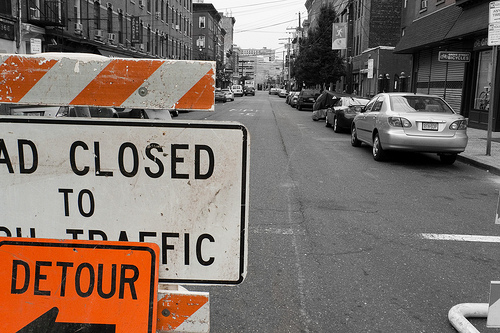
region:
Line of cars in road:
[264, 74, 466, 165]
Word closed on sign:
[68, 136, 220, 193]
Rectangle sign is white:
[1, 119, 244, 288]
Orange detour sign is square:
[8, 249, 155, 326]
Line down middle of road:
[265, 99, 321, 331]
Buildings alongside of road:
[6, 0, 227, 42]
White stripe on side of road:
[408, 212, 499, 257]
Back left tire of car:
[367, 117, 398, 162]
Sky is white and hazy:
[218, 2, 295, 94]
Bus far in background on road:
[241, 74, 260, 99]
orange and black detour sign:
[3, 230, 156, 330]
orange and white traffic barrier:
[3, 49, 227, 331]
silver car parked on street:
[349, 89, 465, 171]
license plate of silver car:
[419, 118, 436, 140]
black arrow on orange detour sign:
[8, 298, 126, 332]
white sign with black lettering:
[2, 118, 253, 283]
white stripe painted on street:
[411, 221, 499, 249]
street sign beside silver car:
[472, 2, 499, 154]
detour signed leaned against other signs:
[0, 232, 165, 332]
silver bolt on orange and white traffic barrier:
[131, 81, 154, 98]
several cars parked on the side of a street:
[257, 3, 496, 332]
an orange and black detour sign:
[2, 238, 159, 329]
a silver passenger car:
[351, 90, 473, 167]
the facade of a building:
[400, 5, 495, 95]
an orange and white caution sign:
[2, 48, 219, 117]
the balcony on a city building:
[21, 0, 68, 31]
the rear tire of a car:
[368, 130, 383, 160]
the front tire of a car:
[347, 121, 359, 146]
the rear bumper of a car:
[385, 131, 471, 156]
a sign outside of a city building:
[437, 48, 471, 65]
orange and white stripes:
[4, 50, 229, 116]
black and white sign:
[0, 113, 257, 288]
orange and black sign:
[1, 232, 161, 332]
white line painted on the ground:
[419, 221, 497, 253]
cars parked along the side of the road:
[321, 88, 471, 168]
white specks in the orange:
[3, 56, 33, 106]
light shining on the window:
[392, 95, 409, 110]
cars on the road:
[216, 72, 261, 105]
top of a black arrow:
[14, 302, 121, 332]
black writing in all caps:
[7, 256, 146, 307]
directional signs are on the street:
[0, 50, 253, 330]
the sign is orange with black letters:
[2, 230, 164, 330]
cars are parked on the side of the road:
[265, 80, 480, 160]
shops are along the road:
[271, 42, 498, 142]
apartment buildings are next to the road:
[8, 3, 234, 112]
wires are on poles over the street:
[218, 0, 313, 98]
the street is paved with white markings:
[200, 88, 499, 332]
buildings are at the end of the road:
[231, 39, 291, 96]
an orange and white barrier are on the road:
[1, 48, 220, 120]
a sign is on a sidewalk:
[483, 1, 499, 166]